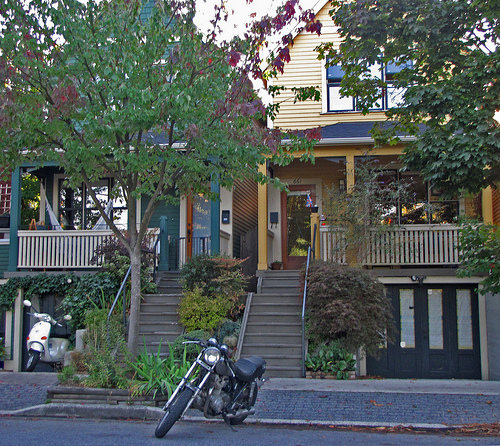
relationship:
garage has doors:
[354, 265, 499, 384] [367, 282, 479, 378]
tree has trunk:
[3, 0, 314, 378] [127, 257, 141, 382]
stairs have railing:
[235, 263, 312, 378] [301, 244, 313, 372]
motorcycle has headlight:
[150, 339, 268, 435] [200, 345, 226, 369]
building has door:
[252, 2, 498, 276] [279, 182, 320, 270]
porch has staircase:
[255, 149, 494, 273] [235, 263, 312, 378]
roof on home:
[263, 120, 499, 146] [256, 1, 498, 380]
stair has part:
[248, 301, 305, 314] [268, 311, 284, 320]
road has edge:
[0, 414, 499, 444] [2, 398, 499, 435]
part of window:
[335, 100, 345, 109] [319, 41, 412, 117]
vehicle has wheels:
[150, 339, 268, 435] [151, 381, 262, 434]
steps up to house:
[256, 266, 308, 293] [252, 2, 498, 276]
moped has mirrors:
[20, 299, 73, 376] [20, 297, 76, 324]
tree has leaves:
[3, 0, 314, 378] [208, 131, 245, 160]